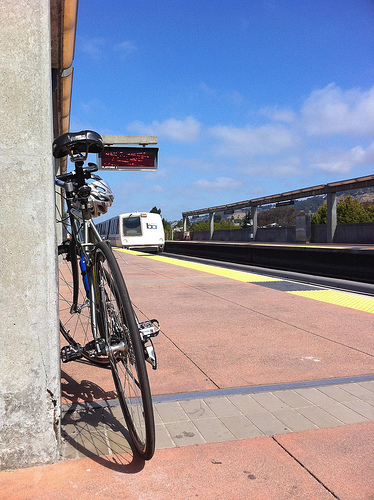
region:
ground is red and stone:
[121, 258, 327, 480]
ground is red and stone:
[163, 297, 295, 448]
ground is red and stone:
[176, 330, 357, 490]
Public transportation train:
[92, 197, 172, 247]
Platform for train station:
[168, 185, 373, 254]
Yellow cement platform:
[133, 247, 369, 314]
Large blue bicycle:
[47, 123, 187, 463]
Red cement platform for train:
[116, 259, 235, 388]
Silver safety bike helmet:
[65, 176, 123, 222]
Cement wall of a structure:
[1, 5, 79, 495]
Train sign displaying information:
[91, 124, 171, 181]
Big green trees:
[310, 195, 368, 227]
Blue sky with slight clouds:
[114, 10, 372, 156]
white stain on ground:
[284, 330, 337, 388]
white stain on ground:
[286, 340, 335, 369]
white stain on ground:
[277, 347, 351, 396]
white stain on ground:
[290, 332, 358, 415]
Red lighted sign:
[96, 138, 163, 171]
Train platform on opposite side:
[180, 196, 365, 256]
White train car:
[94, 207, 191, 250]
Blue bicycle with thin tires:
[20, 129, 171, 469]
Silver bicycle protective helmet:
[65, 178, 114, 219]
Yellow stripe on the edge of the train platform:
[114, 240, 372, 322]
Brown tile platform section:
[40, 371, 373, 455]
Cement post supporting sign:
[100, 127, 160, 147]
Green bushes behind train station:
[174, 211, 372, 236]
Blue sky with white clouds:
[137, 49, 372, 190]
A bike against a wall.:
[47, 103, 194, 426]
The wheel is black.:
[88, 240, 171, 449]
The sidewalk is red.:
[173, 300, 246, 357]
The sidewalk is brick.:
[170, 393, 267, 433]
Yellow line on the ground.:
[297, 282, 368, 324]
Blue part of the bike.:
[74, 252, 104, 293]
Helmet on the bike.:
[76, 168, 119, 218]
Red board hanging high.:
[96, 127, 163, 176]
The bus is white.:
[108, 212, 179, 258]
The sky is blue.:
[152, 39, 296, 110]